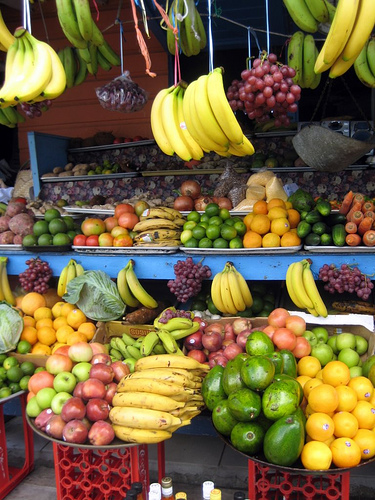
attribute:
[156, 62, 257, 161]
bananas — yellow, hanging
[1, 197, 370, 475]
fruit — ripe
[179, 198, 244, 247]
fruit — green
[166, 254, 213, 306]
grapes — purple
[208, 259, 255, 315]
bananas — yellow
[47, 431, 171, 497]
crate — red, plastic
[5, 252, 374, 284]
wood — blue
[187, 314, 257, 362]
apples — red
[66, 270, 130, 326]
vegetable — leafy, green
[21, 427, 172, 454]
tray — round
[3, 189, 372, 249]
vegetables — ripe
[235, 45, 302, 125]
grapes — hanging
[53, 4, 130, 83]
plantains — hanging, pretty, ripe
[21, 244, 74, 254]
container — black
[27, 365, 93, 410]
apples — green